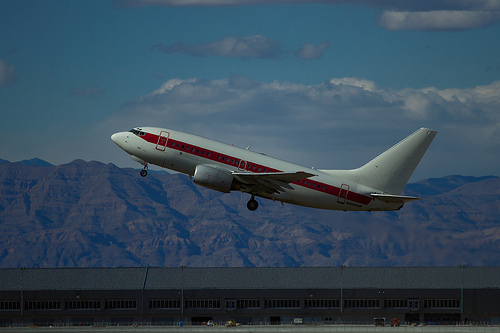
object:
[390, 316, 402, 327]
cars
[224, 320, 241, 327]
cars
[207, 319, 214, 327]
cars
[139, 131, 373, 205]
stripe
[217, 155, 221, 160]
window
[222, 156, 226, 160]
window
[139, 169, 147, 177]
wheel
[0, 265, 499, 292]
roof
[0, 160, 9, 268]
hills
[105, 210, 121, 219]
mountains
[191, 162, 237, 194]
engine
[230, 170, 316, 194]
wing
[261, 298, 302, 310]
windows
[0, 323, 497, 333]
ground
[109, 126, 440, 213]
airplane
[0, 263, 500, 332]
airport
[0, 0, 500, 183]
cloudy sky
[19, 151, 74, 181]
two men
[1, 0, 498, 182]
sky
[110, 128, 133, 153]
nose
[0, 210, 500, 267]
mountains airplane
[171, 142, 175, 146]
window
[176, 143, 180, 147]
window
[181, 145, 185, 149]
window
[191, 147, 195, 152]
window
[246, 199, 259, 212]
wheel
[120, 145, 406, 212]
bottom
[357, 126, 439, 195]
tail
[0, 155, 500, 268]
mountain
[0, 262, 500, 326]
building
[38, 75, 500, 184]
cloud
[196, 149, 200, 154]
window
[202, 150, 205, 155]
window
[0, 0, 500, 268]
background